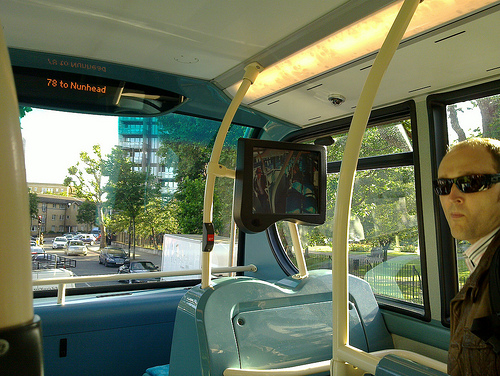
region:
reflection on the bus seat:
[202, 275, 359, 365]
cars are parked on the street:
[50, 222, 166, 282]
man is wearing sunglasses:
[415, 126, 499, 256]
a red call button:
[201, 232, 224, 244]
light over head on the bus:
[225, 3, 429, 105]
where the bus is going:
[17, 70, 114, 104]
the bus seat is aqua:
[198, 255, 373, 354]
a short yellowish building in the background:
[8, 169, 93, 230]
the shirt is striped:
[453, 229, 498, 282]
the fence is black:
[347, 252, 422, 297]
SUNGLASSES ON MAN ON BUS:
[418, 166, 494, 194]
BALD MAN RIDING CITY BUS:
[448, 138, 498, 375]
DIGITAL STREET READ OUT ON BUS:
[33, 66, 118, 107]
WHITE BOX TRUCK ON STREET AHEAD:
[162, 224, 260, 295]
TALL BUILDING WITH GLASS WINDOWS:
[114, 103, 219, 250]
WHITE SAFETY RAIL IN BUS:
[24, 250, 279, 302]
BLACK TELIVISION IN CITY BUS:
[216, 125, 354, 229]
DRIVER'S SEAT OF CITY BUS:
[1, 33, 33, 361]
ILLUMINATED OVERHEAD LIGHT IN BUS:
[232, 36, 378, 98]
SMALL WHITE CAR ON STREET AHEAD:
[50, 232, 77, 248]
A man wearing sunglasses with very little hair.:
[432, 135, 499, 374]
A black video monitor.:
[235, 133, 327, 232]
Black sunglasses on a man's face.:
[425, 170, 498, 195]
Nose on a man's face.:
[447, 182, 468, 205]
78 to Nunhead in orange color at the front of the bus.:
[43, 74, 106, 96]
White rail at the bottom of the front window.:
[32, 261, 262, 306]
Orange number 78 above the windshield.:
[45, 74, 57, 88]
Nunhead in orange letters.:
[67, 78, 110, 95]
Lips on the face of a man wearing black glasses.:
[447, 206, 466, 222]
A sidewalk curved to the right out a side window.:
[362, 242, 421, 301]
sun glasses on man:
[432, 175, 486, 192]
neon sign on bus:
[42, 72, 107, 95]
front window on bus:
[57, 136, 157, 233]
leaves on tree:
[109, 167, 149, 222]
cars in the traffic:
[100, 245, 136, 271]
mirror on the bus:
[235, 143, 316, 226]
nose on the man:
[446, 197, 466, 207]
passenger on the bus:
[430, 132, 498, 374]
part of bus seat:
[232, 295, 312, 346]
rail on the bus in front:
[55, 272, 149, 297]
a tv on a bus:
[185, 106, 347, 283]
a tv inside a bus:
[161, 82, 428, 286]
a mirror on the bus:
[4, 40, 246, 167]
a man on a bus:
[294, 72, 495, 342]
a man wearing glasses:
[409, 139, 499, 277]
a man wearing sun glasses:
[403, 125, 498, 247]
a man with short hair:
[399, 117, 497, 264]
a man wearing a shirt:
[411, 120, 499, 317]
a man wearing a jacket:
[377, 141, 498, 373]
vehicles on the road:
[47, 210, 166, 297]